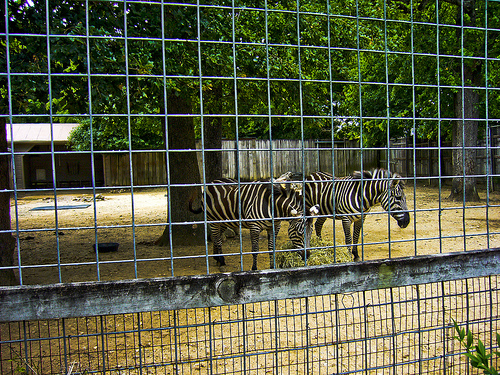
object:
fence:
[4, 1, 495, 160]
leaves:
[237, 26, 279, 70]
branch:
[159, 79, 197, 107]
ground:
[192, 264, 403, 347]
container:
[92, 237, 121, 253]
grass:
[281, 244, 358, 274]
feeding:
[291, 243, 315, 261]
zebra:
[188, 172, 336, 275]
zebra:
[301, 160, 421, 266]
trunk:
[160, 108, 226, 249]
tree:
[103, 7, 215, 145]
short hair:
[250, 176, 303, 202]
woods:
[204, 130, 221, 161]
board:
[229, 132, 317, 176]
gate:
[376, 138, 439, 176]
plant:
[448, 309, 500, 373]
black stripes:
[331, 179, 360, 208]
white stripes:
[210, 191, 228, 207]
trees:
[365, 23, 494, 148]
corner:
[478, 25, 500, 117]